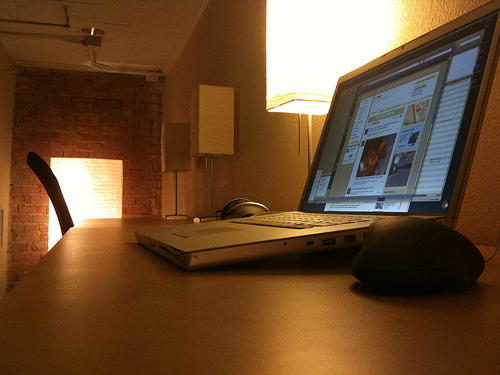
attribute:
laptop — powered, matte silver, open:
[132, 1, 499, 275]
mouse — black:
[343, 214, 487, 297]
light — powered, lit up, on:
[261, 1, 383, 121]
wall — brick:
[161, 1, 499, 285]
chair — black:
[23, 149, 76, 238]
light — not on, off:
[186, 83, 238, 161]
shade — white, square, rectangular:
[158, 118, 195, 175]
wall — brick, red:
[9, 66, 164, 285]